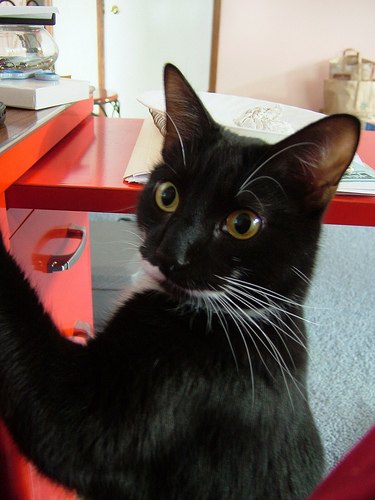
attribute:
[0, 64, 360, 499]
cat — black, white, curious, climbing, staring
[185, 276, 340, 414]
whiskers — long, white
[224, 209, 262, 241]
eye — wide open, yellow, green, brown black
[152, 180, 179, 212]
eye — wide open, yellow, green, brown black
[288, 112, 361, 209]
ear — pink inside, black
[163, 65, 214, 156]
ear — pink inside, black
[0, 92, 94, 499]
dresser — red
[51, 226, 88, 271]
handle — metal, gray, silver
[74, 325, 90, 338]
handle — metal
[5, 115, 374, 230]
desk — red, sliding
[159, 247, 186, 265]
nose — black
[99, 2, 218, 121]
door — white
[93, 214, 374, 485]
carpet — blue, white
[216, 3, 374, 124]
wall — pink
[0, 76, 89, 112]
plate — white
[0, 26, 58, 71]
bottle — colorless